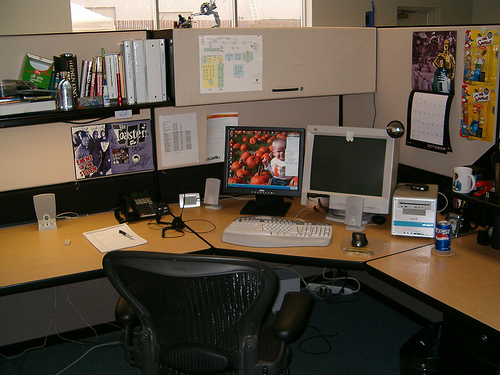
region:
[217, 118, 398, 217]
One computer screen is on and the other one is off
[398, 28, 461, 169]
Calendar has star wars characters on it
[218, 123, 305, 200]
Computer screen has pumpkins and a baby on it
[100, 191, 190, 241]
Black phone has a headset attached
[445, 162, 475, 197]
Coffee mug to the right of the computer is white and has a picture of a man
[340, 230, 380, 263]
Black mouse is on top of a clear mouse pad with a gel wrist guard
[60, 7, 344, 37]
Open window showing outside is in the background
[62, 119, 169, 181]
Poster says Toaster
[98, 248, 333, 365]
Computer chair is black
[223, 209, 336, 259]
Keyboard is white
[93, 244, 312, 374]
black office desk chair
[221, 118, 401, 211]
duel screen computer monitors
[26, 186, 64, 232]
white speaker volume control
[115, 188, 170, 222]
black office desk phone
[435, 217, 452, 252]
small can of soda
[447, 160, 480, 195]
small white coffee mug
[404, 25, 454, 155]
star wars yearly calendar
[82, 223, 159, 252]
pen and paper pad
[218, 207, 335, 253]
key board for computer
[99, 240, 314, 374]
black ergonomical desk chair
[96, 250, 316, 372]
a black office task chair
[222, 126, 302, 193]
a computer monitor with black trim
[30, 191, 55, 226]
a gray speaker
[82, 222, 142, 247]
a pen and paper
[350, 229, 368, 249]
a black computer mouse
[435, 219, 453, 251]
a soft drink can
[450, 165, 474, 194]
a white coffee mug with a colorful decoration on it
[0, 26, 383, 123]
a beige overhead storage area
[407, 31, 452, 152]
a calendar with a photo on top and the dates at the bottom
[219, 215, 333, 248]
a computer keyboard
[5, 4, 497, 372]
Interior shot, with natural daylight.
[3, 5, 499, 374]
Close-up of building interior, office, style.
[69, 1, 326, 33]
Bottom portion of window, allowing natural light in.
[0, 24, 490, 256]
Office cubicle, with buff walls, shelving and cubby space.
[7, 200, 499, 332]
Wooden desk space, in three sections.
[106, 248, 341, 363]
High-backed, black office chair.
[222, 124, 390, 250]
Keyboard and desktop monitors, one lit.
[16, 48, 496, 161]
Books, binders, supplies, papers and calendar.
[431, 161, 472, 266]
Soda bottle and cup.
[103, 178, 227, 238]
Landline and cell phone and dock, beside small item, possibly clock.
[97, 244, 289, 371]
black office chair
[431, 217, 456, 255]
can of pepsi sitting on a desk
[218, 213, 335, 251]
computer keyboard with wrist rest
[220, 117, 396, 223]
two computer monitors side by side on a desk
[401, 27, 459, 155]
Star Wars wall calendar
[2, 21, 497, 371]
inside of an office cubical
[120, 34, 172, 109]
white binders on a shelf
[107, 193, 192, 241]
office phone with headset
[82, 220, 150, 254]
white notepad and pen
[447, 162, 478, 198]
white mug with a picture of a person